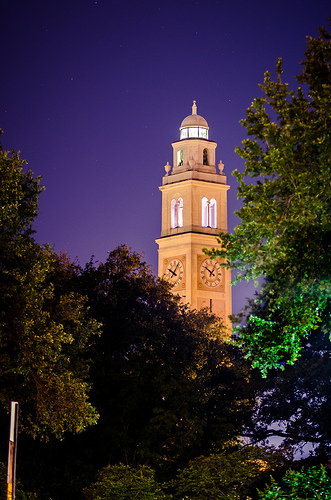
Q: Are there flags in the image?
A: No, there are no flags.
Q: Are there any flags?
A: No, there are no flags.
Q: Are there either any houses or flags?
A: No, there are no flags or houses.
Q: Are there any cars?
A: No, there are no cars.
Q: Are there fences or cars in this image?
A: No, there are no cars or fences.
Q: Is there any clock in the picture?
A: Yes, there is a clock.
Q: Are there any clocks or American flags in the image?
A: Yes, there is a clock.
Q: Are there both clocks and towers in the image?
A: Yes, there are both a clock and a tower.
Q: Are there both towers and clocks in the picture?
A: Yes, there are both a clock and a tower.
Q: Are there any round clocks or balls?
A: Yes, there is a round clock.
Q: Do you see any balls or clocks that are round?
A: Yes, the clock is round.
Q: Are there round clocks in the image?
A: Yes, there is a round clock.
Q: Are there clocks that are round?
A: Yes, there is a clock that is round.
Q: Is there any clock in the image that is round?
A: Yes, there is a clock that is round.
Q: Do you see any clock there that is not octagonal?
A: Yes, there is an round clock.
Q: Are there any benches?
A: No, there are no benches.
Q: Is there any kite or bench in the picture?
A: No, there are no benches or kites.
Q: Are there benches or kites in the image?
A: No, there are no benches or kites.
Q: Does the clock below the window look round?
A: Yes, the clock is round.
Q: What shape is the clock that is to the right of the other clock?
A: The clock is round.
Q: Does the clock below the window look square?
A: No, the clock is round.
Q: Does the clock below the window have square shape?
A: No, the clock is round.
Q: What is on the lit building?
A: The clock is on the tower.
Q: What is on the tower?
A: The clock is on the tower.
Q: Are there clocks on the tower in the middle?
A: Yes, there is a clock on the tower.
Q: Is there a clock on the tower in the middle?
A: Yes, there is a clock on the tower.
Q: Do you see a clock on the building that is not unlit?
A: Yes, there is a clock on the tower.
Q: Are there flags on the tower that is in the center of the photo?
A: No, there is a clock on the tower.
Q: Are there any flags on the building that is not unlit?
A: No, there is a clock on the tower.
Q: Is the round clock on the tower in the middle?
A: Yes, the clock is on the tower.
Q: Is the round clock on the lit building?
A: Yes, the clock is on the tower.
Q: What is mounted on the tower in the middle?
A: The clock is mounted on the tower.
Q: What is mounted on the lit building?
A: The clock is mounted on the tower.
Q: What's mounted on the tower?
A: The clock is mounted on the tower.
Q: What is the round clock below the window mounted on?
A: The clock is mounted on the tower.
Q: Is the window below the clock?
A: No, the clock is below the window.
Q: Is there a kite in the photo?
A: No, there are no kites.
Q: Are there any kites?
A: No, there are no kites.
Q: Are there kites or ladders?
A: No, there are no kites or ladders.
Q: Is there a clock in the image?
A: Yes, there is a clock.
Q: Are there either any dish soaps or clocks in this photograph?
A: Yes, there is a clock.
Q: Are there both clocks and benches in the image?
A: No, there is a clock but no benches.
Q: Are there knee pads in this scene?
A: No, there are no knee pads.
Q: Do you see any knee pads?
A: No, there are no knee pads.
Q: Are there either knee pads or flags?
A: No, there are no knee pads or flags.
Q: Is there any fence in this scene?
A: No, there are no fences.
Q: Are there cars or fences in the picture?
A: No, there are no fences or cars.